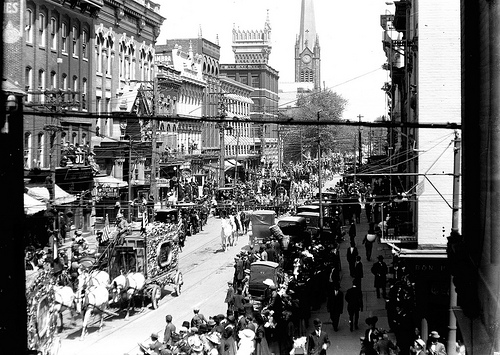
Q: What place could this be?
A: It is a road.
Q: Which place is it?
A: It is a road.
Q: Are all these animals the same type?
A: Yes, all the animals are horses.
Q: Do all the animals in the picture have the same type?
A: Yes, all the animals are horses.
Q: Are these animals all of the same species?
A: Yes, all the animals are horses.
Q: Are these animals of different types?
A: No, all the animals are horses.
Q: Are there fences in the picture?
A: No, there are no fences.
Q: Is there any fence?
A: No, there are no fences.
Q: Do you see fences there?
A: No, there are no fences.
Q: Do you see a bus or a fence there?
A: No, there are no fences or buses.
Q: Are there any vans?
A: No, there are no vans.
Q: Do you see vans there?
A: No, there are no vans.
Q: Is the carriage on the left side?
A: Yes, the carriage is on the left of the image.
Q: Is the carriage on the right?
A: No, the carriage is on the left of the image.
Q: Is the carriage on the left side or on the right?
A: The carriage is on the left of the image.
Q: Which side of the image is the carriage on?
A: The carriage is on the left of the image.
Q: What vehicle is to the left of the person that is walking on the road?
A: The vehicle is a carriage.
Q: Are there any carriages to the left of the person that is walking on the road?
A: Yes, there is a carriage to the left of the person.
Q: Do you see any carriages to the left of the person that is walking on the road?
A: Yes, there is a carriage to the left of the person.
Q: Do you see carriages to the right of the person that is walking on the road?
A: No, the carriage is to the left of the person.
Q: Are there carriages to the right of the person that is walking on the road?
A: No, the carriage is to the left of the person.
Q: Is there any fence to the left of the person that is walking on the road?
A: No, there is a carriage to the left of the person.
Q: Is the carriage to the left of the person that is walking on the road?
A: Yes, the carriage is to the left of the person.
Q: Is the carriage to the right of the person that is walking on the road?
A: No, the carriage is to the left of the person.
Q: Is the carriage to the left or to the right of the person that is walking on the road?
A: The carriage is to the left of the person.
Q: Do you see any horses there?
A: Yes, there is a horse.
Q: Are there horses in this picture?
A: Yes, there is a horse.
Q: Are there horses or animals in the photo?
A: Yes, there is a horse.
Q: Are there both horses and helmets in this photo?
A: No, there is a horse but no helmets.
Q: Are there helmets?
A: No, there are no helmets.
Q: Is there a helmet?
A: No, there are no helmets.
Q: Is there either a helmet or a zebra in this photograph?
A: No, there are no helmets or zebras.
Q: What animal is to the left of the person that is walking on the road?
A: The animal is a horse.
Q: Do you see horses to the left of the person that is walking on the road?
A: Yes, there is a horse to the left of the person.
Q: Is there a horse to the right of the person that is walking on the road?
A: No, the horse is to the left of the person.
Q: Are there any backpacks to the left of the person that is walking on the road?
A: No, there is a horse to the left of the person.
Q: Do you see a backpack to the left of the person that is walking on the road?
A: No, there is a horse to the left of the person.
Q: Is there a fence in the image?
A: No, there are no fences.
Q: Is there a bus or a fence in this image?
A: No, there are no fences or buses.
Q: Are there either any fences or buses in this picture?
A: No, there are no fences or buses.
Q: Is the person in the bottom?
A: Yes, the person is in the bottom of the image.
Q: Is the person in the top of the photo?
A: No, the person is in the bottom of the image.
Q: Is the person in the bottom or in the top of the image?
A: The person is in the bottom of the image.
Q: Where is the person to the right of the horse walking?
A: The person is walking on the road.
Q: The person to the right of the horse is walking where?
A: The person is walking on the road.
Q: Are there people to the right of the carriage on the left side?
A: Yes, there is a person to the right of the carriage.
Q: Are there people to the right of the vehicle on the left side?
A: Yes, there is a person to the right of the carriage.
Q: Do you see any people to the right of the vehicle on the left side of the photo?
A: Yes, there is a person to the right of the carriage.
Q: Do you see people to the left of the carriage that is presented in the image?
A: No, the person is to the right of the carriage.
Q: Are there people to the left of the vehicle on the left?
A: No, the person is to the right of the carriage.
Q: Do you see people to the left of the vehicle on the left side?
A: No, the person is to the right of the carriage.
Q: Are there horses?
A: Yes, there is a horse.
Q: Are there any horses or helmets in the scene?
A: Yes, there is a horse.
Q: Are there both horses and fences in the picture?
A: No, there is a horse but no fences.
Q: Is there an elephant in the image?
A: No, there are no elephants.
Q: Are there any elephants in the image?
A: No, there are no elephants.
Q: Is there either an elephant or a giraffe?
A: No, there are no elephants or giraffes.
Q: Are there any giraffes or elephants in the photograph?
A: No, there are no elephants or giraffes.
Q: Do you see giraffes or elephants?
A: No, there are no elephants or giraffes.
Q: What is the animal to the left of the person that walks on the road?
A: The animal is a horse.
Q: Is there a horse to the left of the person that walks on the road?
A: Yes, there is a horse to the left of the person.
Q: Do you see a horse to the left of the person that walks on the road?
A: Yes, there is a horse to the left of the person.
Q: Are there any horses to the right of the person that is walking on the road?
A: No, the horse is to the left of the person.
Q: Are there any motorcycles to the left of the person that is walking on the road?
A: No, there is a horse to the left of the person.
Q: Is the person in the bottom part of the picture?
A: Yes, the person is in the bottom of the image.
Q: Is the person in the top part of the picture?
A: No, the person is in the bottom of the image.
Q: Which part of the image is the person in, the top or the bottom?
A: The person is in the bottom of the image.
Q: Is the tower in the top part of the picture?
A: Yes, the tower is in the top of the image.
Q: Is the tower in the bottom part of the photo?
A: No, the tower is in the top of the image.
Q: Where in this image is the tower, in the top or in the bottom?
A: The tower is in the top of the image.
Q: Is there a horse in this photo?
A: Yes, there is a horse.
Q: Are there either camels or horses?
A: Yes, there is a horse.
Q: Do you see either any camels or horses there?
A: Yes, there is a horse.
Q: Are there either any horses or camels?
A: Yes, there is a horse.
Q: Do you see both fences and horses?
A: No, there is a horse but no fences.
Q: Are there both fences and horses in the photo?
A: No, there is a horse but no fences.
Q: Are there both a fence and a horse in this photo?
A: No, there is a horse but no fences.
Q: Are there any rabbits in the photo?
A: No, there are no rabbits.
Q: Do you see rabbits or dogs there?
A: No, there are no rabbits or dogs.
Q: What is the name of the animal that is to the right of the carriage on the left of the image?
A: The animal is a horse.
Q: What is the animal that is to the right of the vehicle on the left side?
A: The animal is a horse.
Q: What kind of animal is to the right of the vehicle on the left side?
A: The animal is a horse.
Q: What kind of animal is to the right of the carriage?
A: The animal is a horse.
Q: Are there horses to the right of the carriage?
A: Yes, there is a horse to the right of the carriage.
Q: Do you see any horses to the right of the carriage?
A: Yes, there is a horse to the right of the carriage.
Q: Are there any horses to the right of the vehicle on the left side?
A: Yes, there is a horse to the right of the carriage.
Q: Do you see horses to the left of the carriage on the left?
A: No, the horse is to the right of the carriage.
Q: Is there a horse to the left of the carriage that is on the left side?
A: No, the horse is to the right of the carriage.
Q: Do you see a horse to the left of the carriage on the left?
A: No, the horse is to the right of the carriage.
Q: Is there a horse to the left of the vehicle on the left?
A: No, the horse is to the right of the carriage.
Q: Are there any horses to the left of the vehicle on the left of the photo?
A: No, the horse is to the right of the carriage.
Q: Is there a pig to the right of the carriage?
A: No, there is a horse to the right of the carriage.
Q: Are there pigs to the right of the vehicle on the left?
A: No, there is a horse to the right of the carriage.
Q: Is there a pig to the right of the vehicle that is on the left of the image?
A: No, there is a horse to the right of the carriage.